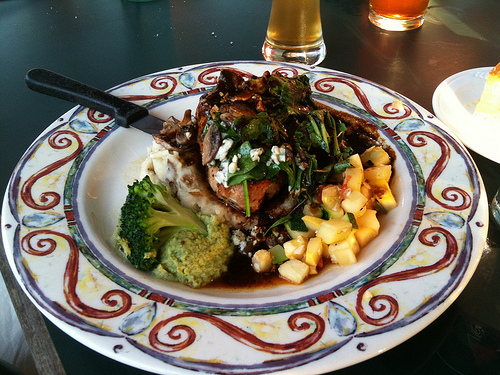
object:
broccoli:
[115, 175, 206, 271]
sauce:
[209, 253, 285, 290]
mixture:
[112, 68, 397, 285]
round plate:
[72, 91, 418, 309]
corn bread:
[473, 66, 500, 126]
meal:
[114, 69, 398, 289]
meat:
[215, 69, 288, 115]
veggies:
[114, 176, 235, 290]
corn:
[246, 163, 389, 286]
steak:
[146, 134, 276, 231]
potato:
[329, 216, 361, 266]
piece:
[271, 183, 394, 284]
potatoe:
[319, 220, 352, 242]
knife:
[24, 68, 165, 135]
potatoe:
[251, 238, 347, 285]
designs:
[2, 61, 481, 375]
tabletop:
[0, 0, 500, 375]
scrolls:
[333, 61, 490, 347]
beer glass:
[261, 0, 328, 66]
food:
[115, 68, 397, 289]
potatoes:
[174, 169, 226, 216]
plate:
[0, 61, 490, 375]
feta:
[172, 145, 290, 231]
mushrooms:
[203, 106, 339, 219]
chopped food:
[251, 145, 396, 284]